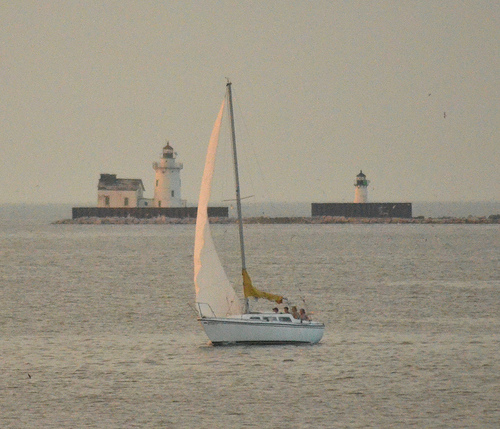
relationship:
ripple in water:
[28, 246, 121, 351] [73, 239, 139, 305]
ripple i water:
[28, 246, 121, 351] [73, 239, 139, 305]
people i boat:
[272, 304, 307, 318] [164, 255, 364, 380]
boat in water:
[164, 255, 364, 380] [73, 239, 139, 305]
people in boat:
[272, 304, 307, 318] [164, 255, 364, 380]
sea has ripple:
[76, 282, 149, 336] [28, 246, 121, 351]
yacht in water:
[158, 82, 331, 359] [73, 239, 139, 305]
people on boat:
[164, 255, 364, 380] [192, 79, 330, 343]